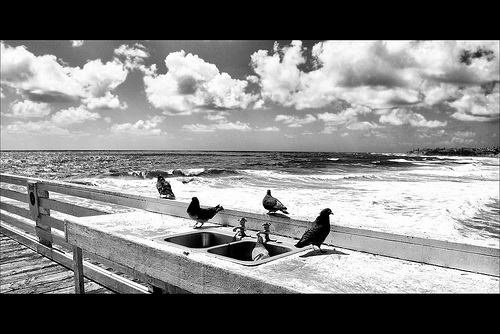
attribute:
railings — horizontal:
[2, 162, 497, 290]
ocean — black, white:
[8, 143, 499, 249]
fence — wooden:
[6, 169, 224, 290]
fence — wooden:
[3, 181, 449, 296]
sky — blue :
[131, 41, 272, 111]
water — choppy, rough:
[1, 149, 499, 247]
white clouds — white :
[1, 40, 498, 127]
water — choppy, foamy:
[5, 144, 498, 236]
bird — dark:
[137, 165, 365, 286]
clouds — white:
[142, 47, 259, 112]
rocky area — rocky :
[412, 141, 489, 165]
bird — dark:
[243, 182, 359, 260]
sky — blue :
[83, 61, 375, 161]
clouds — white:
[0, 38, 500, 150]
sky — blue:
[0, 38, 498, 153]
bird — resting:
[258, 187, 282, 211]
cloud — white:
[438, 63, 477, 107]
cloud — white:
[304, 89, 331, 120]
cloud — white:
[372, 105, 432, 132]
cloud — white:
[308, 59, 345, 99]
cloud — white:
[334, 55, 393, 96]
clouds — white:
[2, 43, 130, 108]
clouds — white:
[32, 85, 132, 133]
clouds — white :
[140, 51, 259, 123]